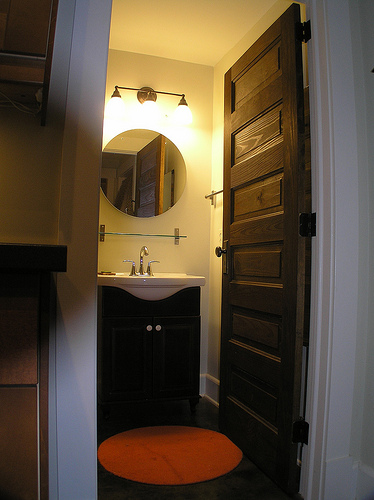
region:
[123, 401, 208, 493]
a round orange rug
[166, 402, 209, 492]
a round orange rug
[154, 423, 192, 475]
a round orange rug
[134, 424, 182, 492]
a round orange rug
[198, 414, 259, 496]
a round orange rug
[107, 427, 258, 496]
orange carpet on black floor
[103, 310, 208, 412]
two doors under sink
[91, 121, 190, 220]
circular mirror over sink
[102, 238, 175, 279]
silver faucet on white sink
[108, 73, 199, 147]
three lights above mirror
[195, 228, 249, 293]
metallic doorknob on black door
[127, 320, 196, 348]
white knobs on cabinet doors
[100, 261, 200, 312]
white sink on black cabinet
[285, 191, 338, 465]
black hinges on door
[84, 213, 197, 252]
silver towel rack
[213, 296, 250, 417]
the door is open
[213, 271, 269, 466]
the door is open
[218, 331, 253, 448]
the door is open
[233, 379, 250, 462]
the door is open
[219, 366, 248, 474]
the door is open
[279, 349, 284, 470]
the door is open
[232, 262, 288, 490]
the door is open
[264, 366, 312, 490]
the door is open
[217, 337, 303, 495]
the door is open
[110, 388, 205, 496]
an orange rug on the floor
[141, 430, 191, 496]
an orange rug on the floor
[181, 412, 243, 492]
an orange rug on the floor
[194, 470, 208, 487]
an orange rug on the floor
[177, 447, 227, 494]
an orange rug on the floor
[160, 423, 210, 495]
an orange rug on the floor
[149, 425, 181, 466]
an orange rug on the floor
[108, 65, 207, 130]
Light fixture with three bulbs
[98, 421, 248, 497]
Small round floor rug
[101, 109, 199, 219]
Round mirror hanging on the wall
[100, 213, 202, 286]
Silver towel rack mounted above sink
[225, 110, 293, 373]
Dark colored wooden door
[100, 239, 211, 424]
White sink on a dark wooden base.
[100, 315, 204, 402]
Two cabinet doors underneath the sink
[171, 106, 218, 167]
Glare on the wall from light fixture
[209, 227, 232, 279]
Old fashioned doorknob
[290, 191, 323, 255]
Hinge on bathroom door